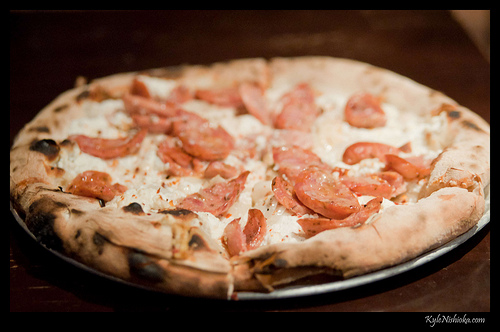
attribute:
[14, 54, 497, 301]
pizza — ready, delicious, round, personal, sliced, cooked properly, cooked, cut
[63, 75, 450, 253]
cheese — white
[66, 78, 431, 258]
pepperoni — red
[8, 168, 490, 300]
dish — white, silver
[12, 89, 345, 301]
spots — burnt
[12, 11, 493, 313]
table — wooden, dark brown, brown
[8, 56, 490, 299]
crust — burnt, burned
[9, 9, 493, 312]
background — blurry